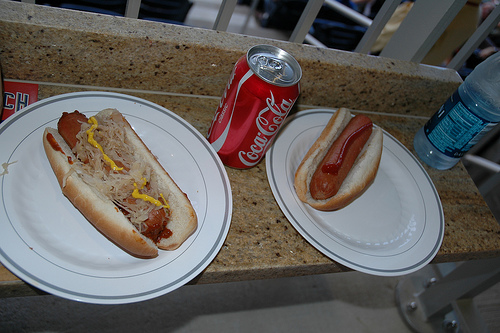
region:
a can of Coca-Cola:
[206, 43, 301, 170]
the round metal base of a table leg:
[396, 272, 458, 331]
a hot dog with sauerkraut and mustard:
[44, 107, 197, 258]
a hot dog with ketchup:
[294, 105, 384, 210]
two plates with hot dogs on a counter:
[0, 92, 445, 305]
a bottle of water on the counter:
[412, 65, 498, 170]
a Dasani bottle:
[413, 65, 498, 170]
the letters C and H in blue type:
[0, 90, 30, 113]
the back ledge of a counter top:
[1, 0, 465, 114]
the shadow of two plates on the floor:
[3, 270, 435, 330]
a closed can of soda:
[204, 40, 305, 182]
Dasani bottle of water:
[410, 48, 496, 170]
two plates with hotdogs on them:
[4, 84, 450, 307]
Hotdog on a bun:
[292, 104, 388, 214]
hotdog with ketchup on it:
[293, 105, 384, 206]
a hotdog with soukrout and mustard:
[37, 104, 203, 265]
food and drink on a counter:
[0, 7, 499, 307]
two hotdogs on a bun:
[37, 104, 385, 259]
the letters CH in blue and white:
[2, 81, 32, 118]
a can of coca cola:
[198, 41, 304, 177]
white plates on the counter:
[1, 88, 446, 273]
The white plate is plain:
[0, 88, 231, 303]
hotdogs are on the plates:
[42, 105, 387, 256]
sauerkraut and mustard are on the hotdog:
[30, 110, 201, 257]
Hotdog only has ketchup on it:
[293, 106, 381, 212]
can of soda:
[200, 45, 300, 170]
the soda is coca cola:
[190, 45, 296, 165]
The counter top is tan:
[5, 3, 494, 295]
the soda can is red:
[207, 45, 303, 171]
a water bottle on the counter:
[401, 48, 498, 170]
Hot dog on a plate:
[1, 93, 234, 307]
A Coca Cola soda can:
[203, 42, 303, 171]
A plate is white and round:
[262, 103, 445, 280]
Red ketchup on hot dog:
[319, 118, 373, 178]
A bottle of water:
[414, 46, 498, 171]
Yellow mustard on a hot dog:
[81, 112, 169, 211]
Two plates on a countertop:
[1, 87, 448, 307]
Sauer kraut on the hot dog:
[60, 110, 177, 226]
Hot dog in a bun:
[291, 99, 387, 214]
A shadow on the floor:
[1, 272, 414, 331]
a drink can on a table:
[195, 43, 305, 194]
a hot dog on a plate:
[0, 107, 190, 280]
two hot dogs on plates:
[1, 119, 449, 266]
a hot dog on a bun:
[293, 90, 411, 215]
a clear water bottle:
[411, 39, 490, 187]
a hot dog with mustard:
[39, 117, 167, 217]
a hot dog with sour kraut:
[36, 118, 163, 257]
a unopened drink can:
[208, 39, 302, 176]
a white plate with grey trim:
[253, 185, 464, 285]